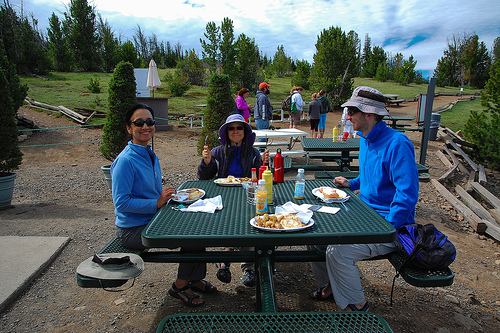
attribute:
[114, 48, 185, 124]
umbrella — folded, white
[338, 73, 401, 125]
hat — tan, floppy, grey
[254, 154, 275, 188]
ketchup — red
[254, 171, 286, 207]
mustard — yellow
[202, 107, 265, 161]
woman — smiling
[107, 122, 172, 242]
man — sitting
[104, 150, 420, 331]
table — metal, green, mesh, outdoors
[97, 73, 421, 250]
people — enjoying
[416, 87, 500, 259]
edges — wooden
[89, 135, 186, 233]
jacket — light blue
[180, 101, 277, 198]
female — smiling, sitting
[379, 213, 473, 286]
backpack — blue, black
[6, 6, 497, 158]
trees — green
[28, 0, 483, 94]
clouds — white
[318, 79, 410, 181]
man — watching, sitting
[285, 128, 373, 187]
bench — green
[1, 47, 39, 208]
tree — potted